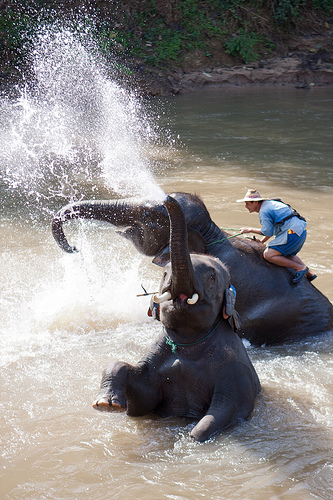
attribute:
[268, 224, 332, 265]
shorts — blue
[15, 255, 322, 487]
water — brown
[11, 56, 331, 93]
riverside — mud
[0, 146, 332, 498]
water — brown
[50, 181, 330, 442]
elephants — gray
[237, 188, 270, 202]
hat — tan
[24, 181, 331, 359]
elephant — grey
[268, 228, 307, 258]
shorts — blue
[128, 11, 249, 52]
plant — green